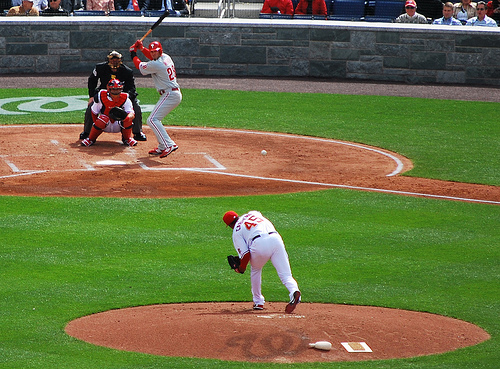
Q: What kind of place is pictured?
A: It is a field.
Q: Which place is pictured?
A: It is a field.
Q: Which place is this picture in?
A: It is at the field.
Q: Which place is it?
A: It is a field.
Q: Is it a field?
A: Yes, it is a field.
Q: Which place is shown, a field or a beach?
A: It is a field.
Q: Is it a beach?
A: No, it is a field.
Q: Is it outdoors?
A: Yes, it is outdoors.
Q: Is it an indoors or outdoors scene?
A: It is outdoors.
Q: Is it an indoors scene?
A: No, it is outdoors.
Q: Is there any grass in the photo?
A: Yes, there is grass.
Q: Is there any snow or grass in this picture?
A: Yes, there is grass.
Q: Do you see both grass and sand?
A: No, there is grass but no sand.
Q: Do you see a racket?
A: No, there are no rackets.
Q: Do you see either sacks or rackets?
A: No, there are no rackets or sacks.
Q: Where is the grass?
A: The grass is on the field.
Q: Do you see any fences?
A: No, there are no fences.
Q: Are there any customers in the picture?
A: No, there are no customers.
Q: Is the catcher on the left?
A: Yes, the catcher is on the left of the image.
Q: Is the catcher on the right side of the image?
A: No, the catcher is on the left of the image.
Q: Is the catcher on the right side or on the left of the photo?
A: The catcher is on the left of the image.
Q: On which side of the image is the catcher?
A: The catcher is on the left of the image.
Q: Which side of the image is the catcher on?
A: The catcher is on the left of the image.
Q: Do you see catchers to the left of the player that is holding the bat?
A: Yes, there is a catcher to the left of the player.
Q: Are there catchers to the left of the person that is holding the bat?
A: Yes, there is a catcher to the left of the player.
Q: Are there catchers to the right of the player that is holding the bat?
A: No, the catcher is to the left of the player.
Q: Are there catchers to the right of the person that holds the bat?
A: No, the catcher is to the left of the player.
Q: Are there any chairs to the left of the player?
A: No, there is a catcher to the left of the player.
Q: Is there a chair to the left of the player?
A: No, there is a catcher to the left of the player.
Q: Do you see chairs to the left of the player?
A: No, there is a catcher to the left of the player.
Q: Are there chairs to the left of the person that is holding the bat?
A: No, there is a catcher to the left of the player.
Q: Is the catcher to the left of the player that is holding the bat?
A: Yes, the catcher is to the left of the player.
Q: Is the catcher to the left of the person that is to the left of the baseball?
A: Yes, the catcher is to the left of the player.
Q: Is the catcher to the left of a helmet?
A: No, the catcher is to the left of the player.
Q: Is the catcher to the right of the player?
A: No, the catcher is to the left of the player.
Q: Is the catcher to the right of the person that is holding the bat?
A: No, the catcher is to the left of the player.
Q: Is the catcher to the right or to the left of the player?
A: The catcher is to the left of the player.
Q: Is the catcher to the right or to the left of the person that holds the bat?
A: The catcher is to the left of the player.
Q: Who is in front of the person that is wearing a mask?
A: The catcher is in front of the umpire.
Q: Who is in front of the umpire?
A: The catcher is in front of the umpire.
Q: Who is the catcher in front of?
A: The catcher is in front of the umpire.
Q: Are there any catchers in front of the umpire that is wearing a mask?
A: Yes, there is a catcher in front of the umpire.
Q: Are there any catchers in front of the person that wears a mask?
A: Yes, there is a catcher in front of the umpire.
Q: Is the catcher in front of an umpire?
A: Yes, the catcher is in front of an umpire.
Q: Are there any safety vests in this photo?
A: No, there are no safety vests.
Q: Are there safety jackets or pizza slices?
A: No, there are no safety jackets or pizza slices.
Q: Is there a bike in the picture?
A: No, there are no bikes.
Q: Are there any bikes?
A: No, there are no bikes.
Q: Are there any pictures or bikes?
A: No, there are no bikes or pictures.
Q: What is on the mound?
A: The pitcher is on the mound.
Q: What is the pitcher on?
A: The pitcher is on the mound.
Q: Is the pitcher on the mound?
A: Yes, the pitcher is on the mound.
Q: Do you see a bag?
A: No, there are no bags.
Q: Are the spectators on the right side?
A: Yes, the spectators are on the right of the image.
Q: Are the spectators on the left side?
A: No, the spectators are on the right of the image.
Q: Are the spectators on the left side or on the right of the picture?
A: The spectators are on the right of the image.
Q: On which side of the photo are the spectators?
A: The spectators are on the right of the image.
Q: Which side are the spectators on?
A: The spectators are on the right of the image.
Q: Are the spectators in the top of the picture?
A: Yes, the spectators are in the top of the image.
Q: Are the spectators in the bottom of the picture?
A: No, the spectators are in the top of the image.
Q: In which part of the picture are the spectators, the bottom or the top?
A: The spectators are in the top of the image.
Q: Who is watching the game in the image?
A: The spectators are watching the game.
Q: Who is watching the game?
A: The spectators are watching the game.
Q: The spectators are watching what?
A: The spectators are watching the game.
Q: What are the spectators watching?
A: The spectators are watching the game.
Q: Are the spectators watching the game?
A: Yes, the spectators are watching the game.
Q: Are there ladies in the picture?
A: No, there are no ladies.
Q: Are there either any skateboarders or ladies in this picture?
A: No, there are no ladies or skateboarders.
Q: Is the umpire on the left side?
A: Yes, the umpire is on the left of the image.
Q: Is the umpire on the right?
A: No, the umpire is on the left of the image.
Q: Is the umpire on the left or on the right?
A: The umpire is on the left of the image.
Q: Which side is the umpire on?
A: The umpire is on the left of the image.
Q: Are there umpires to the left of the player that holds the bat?
A: Yes, there is an umpire to the left of the player.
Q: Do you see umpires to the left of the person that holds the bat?
A: Yes, there is an umpire to the left of the player.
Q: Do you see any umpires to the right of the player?
A: No, the umpire is to the left of the player.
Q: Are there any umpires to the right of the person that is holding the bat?
A: No, the umpire is to the left of the player.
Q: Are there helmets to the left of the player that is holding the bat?
A: No, there is an umpire to the left of the player.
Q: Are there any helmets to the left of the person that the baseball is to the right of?
A: No, there is an umpire to the left of the player.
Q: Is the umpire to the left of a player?
A: Yes, the umpire is to the left of a player.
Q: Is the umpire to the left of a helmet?
A: No, the umpire is to the left of a player.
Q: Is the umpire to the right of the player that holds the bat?
A: No, the umpire is to the left of the player.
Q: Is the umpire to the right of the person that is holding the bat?
A: No, the umpire is to the left of the player.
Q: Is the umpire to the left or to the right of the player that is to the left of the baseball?
A: The umpire is to the left of the player.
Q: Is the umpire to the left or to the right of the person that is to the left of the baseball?
A: The umpire is to the left of the player.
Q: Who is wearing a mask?
A: The umpire is wearing a mask.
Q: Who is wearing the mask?
A: The umpire is wearing a mask.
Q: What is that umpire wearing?
A: The umpire is wearing a mask.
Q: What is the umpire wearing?
A: The umpire is wearing a mask.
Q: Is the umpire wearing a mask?
A: Yes, the umpire is wearing a mask.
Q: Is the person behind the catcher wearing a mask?
A: Yes, the umpire is wearing a mask.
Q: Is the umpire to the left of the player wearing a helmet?
A: No, the umpire is wearing a mask.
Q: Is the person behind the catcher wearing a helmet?
A: No, the umpire is wearing a mask.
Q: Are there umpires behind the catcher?
A: Yes, there is an umpire behind the catcher.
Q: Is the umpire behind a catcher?
A: Yes, the umpire is behind a catcher.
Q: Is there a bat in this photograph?
A: Yes, there is a bat.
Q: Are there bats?
A: Yes, there is a bat.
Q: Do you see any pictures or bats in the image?
A: Yes, there is a bat.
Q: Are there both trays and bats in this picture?
A: No, there is a bat but no trays.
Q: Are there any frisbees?
A: No, there are no frisbees.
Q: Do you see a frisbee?
A: No, there are no frisbees.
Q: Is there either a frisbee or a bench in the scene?
A: No, there are no frisbees or benches.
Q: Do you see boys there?
A: No, there are no boys.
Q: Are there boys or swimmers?
A: No, there are no boys or swimmers.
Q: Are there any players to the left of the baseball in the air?
A: Yes, there is a player to the left of the baseball.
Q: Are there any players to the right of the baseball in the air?
A: No, the player is to the left of the baseball.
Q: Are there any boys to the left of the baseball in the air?
A: No, there is a player to the left of the baseball.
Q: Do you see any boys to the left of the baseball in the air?
A: No, there is a player to the left of the baseball.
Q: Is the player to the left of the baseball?
A: Yes, the player is to the left of the baseball.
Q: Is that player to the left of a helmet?
A: No, the player is to the left of the baseball.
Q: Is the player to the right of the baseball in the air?
A: No, the player is to the left of the baseball.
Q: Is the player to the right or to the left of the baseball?
A: The player is to the left of the baseball.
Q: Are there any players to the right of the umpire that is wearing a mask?
A: Yes, there is a player to the right of the umpire.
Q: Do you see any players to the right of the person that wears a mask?
A: Yes, there is a player to the right of the umpire.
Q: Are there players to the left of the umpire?
A: No, the player is to the right of the umpire.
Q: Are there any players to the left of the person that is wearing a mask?
A: No, the player is to the right of the umpire.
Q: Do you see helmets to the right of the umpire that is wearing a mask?
A: No, there is a player to the right of the umpire.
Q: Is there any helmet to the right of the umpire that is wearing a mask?
A: No, there is a player to the right of the umpire.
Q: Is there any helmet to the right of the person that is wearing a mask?
A: No, there is a player to the right of the umpire.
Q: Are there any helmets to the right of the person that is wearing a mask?
A: No, there is a player to the right of the umpire.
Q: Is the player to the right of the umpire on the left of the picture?
A: Yes, the player is to the right of the umpire.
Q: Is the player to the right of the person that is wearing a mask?
A: Yes, the player is to the right of the umpire.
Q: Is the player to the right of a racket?
A: No, the player is to the right of the umpire.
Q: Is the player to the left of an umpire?
A: No, the player is to the right of an umpire.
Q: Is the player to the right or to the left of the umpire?
A: The player is to the right of the umpire.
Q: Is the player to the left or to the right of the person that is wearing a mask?
A: The player is to the right of the umpire.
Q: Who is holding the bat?
A: The player is holding the bat.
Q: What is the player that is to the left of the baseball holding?
A: The player is holding the bat.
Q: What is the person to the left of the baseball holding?
A: The player is holding the bat.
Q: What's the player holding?
A: The player is holding the bat.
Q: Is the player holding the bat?
A: Yes, the player is holding the bat.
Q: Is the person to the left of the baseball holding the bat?
A: Yes, the player is holding the bat.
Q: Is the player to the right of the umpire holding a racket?
A: No, the player is holding the bat.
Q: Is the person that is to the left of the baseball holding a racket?
A: No, the player is holding the bat.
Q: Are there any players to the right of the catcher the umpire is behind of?
A: Yes, there is a player to the right of the catcher.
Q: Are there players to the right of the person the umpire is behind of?
A: Yes, there is a player to the right of the catcher.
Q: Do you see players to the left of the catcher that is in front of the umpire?
A: No, the player is to the right of the catcher.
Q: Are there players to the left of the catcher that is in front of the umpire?
A: No, the player is to the right of the catcher.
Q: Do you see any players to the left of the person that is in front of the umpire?
A: No, the player is to the right of the catcher.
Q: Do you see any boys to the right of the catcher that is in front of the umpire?
A: No, there is a player to the right of the catcher.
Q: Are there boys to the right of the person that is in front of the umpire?
A: No, there is a player to the right of the catcher.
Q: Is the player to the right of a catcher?
A: Yes, the player is to the right of a catcher.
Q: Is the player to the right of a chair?
A: No, the player is to the right of a catcher.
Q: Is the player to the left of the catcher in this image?
A: No, the player is to the right of the catcher.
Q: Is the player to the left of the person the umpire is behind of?
A: No, the player is to the right of the catcher.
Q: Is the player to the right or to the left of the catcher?
A: The player is to the right of the catcher.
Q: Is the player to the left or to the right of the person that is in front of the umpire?
A: The player is to the right of the catcher.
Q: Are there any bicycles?
A: No, there are no bicycles.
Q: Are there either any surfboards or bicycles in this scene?
A: No, there are no bicycles or surfboards.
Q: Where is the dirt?
A: The dirt is on the field.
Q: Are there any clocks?
A: No, there are no clocks.